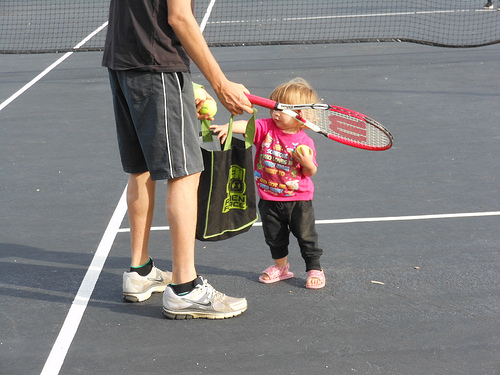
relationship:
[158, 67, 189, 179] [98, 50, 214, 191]
stripes on shorts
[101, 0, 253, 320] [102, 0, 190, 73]
dad wearing black shirt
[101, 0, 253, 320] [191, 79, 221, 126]
dad holding balls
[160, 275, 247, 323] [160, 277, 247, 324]
shoe on foot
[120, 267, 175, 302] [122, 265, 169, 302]
shoe on foot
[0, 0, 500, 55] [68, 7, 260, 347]
net in front of man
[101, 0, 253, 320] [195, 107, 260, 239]
dad holding bag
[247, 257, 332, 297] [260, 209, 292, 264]
chappel on leg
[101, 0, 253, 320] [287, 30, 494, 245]
dad standing in tennis court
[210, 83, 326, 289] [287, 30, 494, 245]
baby standing in tennis court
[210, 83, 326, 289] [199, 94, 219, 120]
baby holding tennis ball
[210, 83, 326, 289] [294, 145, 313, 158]
baby holding tennis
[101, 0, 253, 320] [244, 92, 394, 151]
dad holding racket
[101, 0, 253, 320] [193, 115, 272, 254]
dad holding bag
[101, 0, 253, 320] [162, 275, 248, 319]
dad wearing shoe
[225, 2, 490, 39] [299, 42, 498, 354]
net surrounding field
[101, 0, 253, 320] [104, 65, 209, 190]
dad wearing black shorts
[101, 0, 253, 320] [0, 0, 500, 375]
dad standing on court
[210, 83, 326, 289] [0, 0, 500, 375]
baby standing on court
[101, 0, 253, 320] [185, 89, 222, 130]
dad holding ball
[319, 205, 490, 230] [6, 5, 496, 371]
line on ground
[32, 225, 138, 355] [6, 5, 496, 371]
line on ground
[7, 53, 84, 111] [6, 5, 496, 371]
line on ground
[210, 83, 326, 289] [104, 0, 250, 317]
baby playing with dad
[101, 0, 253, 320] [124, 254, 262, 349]
dad wearing shoes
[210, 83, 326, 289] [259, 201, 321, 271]
baby wearing pants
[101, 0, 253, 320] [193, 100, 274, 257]
dad holding bag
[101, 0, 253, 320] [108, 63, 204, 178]
dad wearing shorts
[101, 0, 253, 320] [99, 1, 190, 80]
dad wearing shirt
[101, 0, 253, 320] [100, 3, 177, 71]
dad has black shirt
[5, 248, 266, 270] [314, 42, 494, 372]
shadow on court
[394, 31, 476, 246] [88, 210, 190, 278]
court has lines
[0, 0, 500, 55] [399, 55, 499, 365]
net on court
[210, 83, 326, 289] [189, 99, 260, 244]
baby reaching into bag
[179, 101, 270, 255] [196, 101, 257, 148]
bag with handles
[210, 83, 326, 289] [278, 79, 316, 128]
baby with hair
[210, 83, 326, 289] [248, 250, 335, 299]
baby wearing pink shoes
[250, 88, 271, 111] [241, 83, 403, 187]
handle of racket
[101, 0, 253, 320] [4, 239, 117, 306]
dad has a shadow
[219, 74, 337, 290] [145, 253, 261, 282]
baby has a shadow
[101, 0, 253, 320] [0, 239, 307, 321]
dad has a shadow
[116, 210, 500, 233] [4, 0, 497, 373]
line on tennis court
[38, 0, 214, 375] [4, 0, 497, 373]
line on tennis court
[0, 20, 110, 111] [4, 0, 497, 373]
line on tennis court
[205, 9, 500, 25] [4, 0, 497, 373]
lines on tennis court